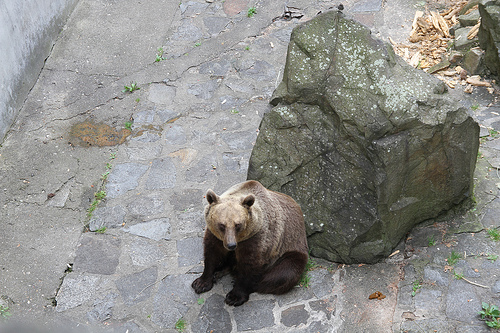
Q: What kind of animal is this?
A: Bear.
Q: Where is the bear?
A: By the rock.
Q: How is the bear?
A: Sitting.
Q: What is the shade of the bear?
A: Brown.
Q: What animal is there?
A: Bear.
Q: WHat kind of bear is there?
A: Grizzly.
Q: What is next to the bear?
A: Rocks.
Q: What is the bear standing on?
A: Concrete.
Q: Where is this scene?
A: Zoo.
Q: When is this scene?
A: Afternoon.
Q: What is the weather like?
A: Fair.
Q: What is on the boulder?
A: Crevices.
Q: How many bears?
A: One.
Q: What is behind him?
A: A rock.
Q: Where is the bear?
A: In a cage.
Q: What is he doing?
A: Sitting.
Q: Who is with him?
A: Nobody.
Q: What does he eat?
A: Fish.